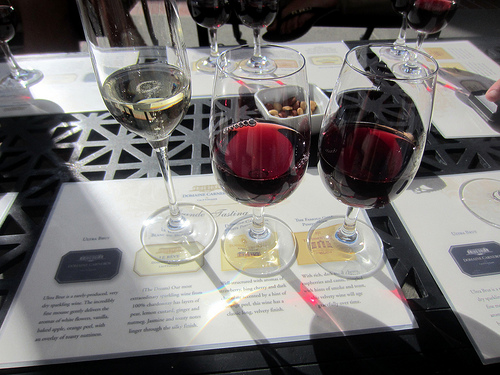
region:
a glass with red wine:
[233, 140, 290, 184]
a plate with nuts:
[313, 93, 323, 113]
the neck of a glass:
[151, 153, 177, 192]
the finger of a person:
[491, 83, 499, 102]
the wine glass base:
[149, 211, 209, 253]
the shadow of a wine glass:
[312, 310, 389, 362]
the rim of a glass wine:
[285, 68, 306, 76]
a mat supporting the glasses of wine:
[67, 203, 109, 233]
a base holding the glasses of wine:
[81, 120, 118, 152]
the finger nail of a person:
[491, 88, 496, 97]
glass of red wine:
[210, 34, 315, 279]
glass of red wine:
[308, 29, 440, 282]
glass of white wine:
[73, 10, 218, 263]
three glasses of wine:
[68, 3, 425, 290]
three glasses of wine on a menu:
[8, 3, 415, 354]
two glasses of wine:
[188, 2, 279, 77]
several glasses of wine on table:
[0, 3, 492, 274]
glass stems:
[136, 193, 386, 285]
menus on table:
[13, 44, 499, 365]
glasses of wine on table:
[3, 3, 493, 370]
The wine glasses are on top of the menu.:
[72, 1, 449, 306]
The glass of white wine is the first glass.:
[76, 1, 457, 243]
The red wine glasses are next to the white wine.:
[78, 4, 428, 203]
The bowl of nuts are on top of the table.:
[241, 71, 331, 144]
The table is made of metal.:
[9, 118, 129, 178]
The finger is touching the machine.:
[447, 62, 499, 139]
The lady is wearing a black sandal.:
[262, 0, 352, 60]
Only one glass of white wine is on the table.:
[42, 2, 451, 244]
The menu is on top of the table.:
[34, 170, 438, 361]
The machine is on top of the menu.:
[437, 62, 498, 137]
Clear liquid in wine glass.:
[112, 68, 171, 144]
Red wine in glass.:
[211, 127, 286, 204]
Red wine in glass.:
[328, 129, 386, 215]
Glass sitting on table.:
[295, 203, 381, 292]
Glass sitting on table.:
[233, 240, 284, 292]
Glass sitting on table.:
[134, 198, 201, 271]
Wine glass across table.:
[11, 43, 62, 116]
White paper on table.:
[406, 205, 498, 302]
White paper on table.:
[98, 231, 346, 322]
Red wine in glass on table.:
[400, 10, 463, 43]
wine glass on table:
[310, 45, 438, 278]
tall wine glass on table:
[72, 0, 217, 277]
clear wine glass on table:
[212, 40, 314, 280]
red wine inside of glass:
[325, 128, 408, 200]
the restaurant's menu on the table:
[400, 171, 495, 361]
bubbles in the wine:
[221, 120, 256, 135]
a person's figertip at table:
[485, 75, 495, 107]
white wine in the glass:
[125, 70, 172, 120]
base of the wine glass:
[136, 200, 212, 260]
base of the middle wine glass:
[220, 213, 295, 283]